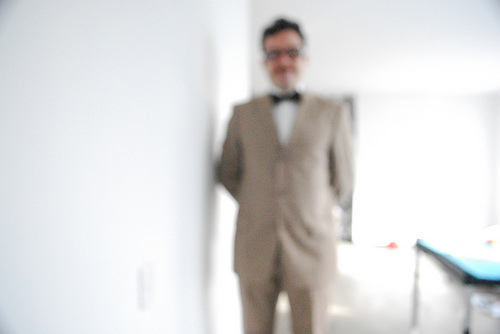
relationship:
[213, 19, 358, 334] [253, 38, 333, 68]
man wearing glasses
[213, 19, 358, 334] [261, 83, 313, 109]
man wearing bow tie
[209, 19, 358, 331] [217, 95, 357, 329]
man wearing suit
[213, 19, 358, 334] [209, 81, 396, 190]
man wearing shirt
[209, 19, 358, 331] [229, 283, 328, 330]
man wearing pants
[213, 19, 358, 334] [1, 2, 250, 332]
man standing by wall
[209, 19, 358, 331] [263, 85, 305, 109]
man wearing bow tie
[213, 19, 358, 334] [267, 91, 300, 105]
man wearing bowtie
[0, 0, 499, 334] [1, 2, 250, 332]
section of wall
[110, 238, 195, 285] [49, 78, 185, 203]
section of wall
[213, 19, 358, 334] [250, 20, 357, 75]
man has glasses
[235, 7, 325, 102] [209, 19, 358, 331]
head belonging to man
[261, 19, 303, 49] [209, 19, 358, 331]
hair belonging to man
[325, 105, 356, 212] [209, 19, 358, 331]
arm belonging to man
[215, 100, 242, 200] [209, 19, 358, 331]
arm belonging to man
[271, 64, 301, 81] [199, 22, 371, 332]
mouth belonging to man